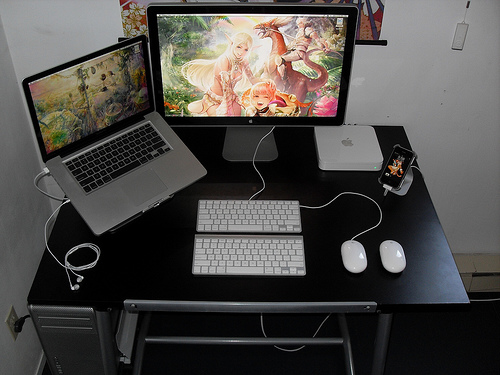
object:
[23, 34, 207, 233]
laptop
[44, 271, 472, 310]
computer desk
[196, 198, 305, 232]
keyboard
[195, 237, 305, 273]
keyboard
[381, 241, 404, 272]
cordless mouse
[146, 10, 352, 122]
computer monitor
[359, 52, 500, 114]
wall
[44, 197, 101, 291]
earbuds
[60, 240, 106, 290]
ear bud headphones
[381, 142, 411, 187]
cell phone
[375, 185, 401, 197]
charger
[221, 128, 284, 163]
base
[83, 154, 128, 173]
laptop keys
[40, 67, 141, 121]
moniter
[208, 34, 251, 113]
girl photo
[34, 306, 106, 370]
computer tower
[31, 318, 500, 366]
ground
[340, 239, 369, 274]
computer mice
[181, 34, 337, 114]
fantasy scene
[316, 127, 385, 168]
wireless router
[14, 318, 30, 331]
plug connected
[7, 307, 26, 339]
outlet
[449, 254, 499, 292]
wall heater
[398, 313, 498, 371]
floor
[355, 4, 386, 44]
picture on wall